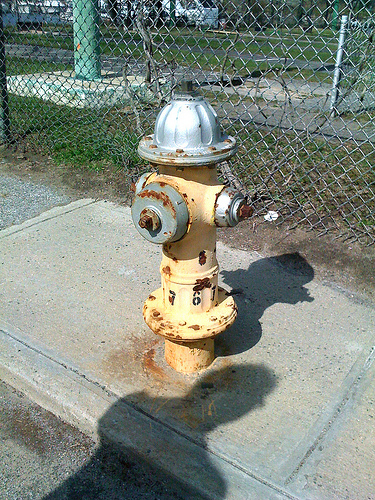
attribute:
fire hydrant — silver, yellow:
[137, 179, 262, 380]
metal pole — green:
[68, 3, 102, 73]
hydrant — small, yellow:
[154, 61, 255, 253]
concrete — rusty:
[2, 146, 372, 499]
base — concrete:
[5, 67, 174, 109]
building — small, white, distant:
[3, 1, 217, 27]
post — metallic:
[327, 13, 347, 116]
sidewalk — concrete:
[7, 173, 369, 464]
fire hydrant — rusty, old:
[124, 76, 261, 372]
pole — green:
[68, 0, 100, 79]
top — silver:
[136, 77, 234, 167]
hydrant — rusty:
[129, 78, 255, 373]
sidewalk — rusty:
[1, 168, 373, 498]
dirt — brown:
[1, 148, 373, 297]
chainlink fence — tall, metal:
[0, 1, 373, 247]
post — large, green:
[72, 1, 100, 79]